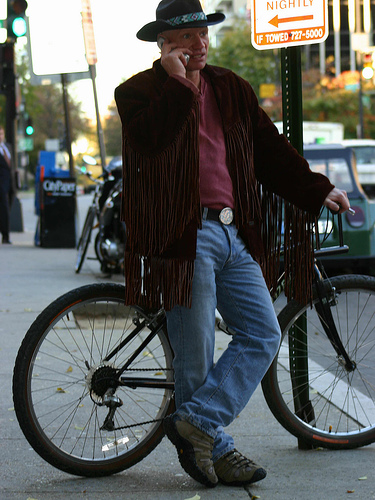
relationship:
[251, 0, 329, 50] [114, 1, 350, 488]
sign behind man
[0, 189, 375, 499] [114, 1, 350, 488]
sidewalk under man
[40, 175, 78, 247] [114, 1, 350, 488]
newspaper box behind man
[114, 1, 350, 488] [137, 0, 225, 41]
man wearing hat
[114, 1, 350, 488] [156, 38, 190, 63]
man talking on phone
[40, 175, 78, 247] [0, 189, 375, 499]
newspaper box on sidewalk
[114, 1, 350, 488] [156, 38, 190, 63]
man on phone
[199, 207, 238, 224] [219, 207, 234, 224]
belt and belt buckle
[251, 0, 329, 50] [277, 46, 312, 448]
sign on pole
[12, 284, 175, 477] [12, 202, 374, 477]
tire on bicycle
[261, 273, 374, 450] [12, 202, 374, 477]
front tire on bicycle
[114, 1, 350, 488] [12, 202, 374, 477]
man leaning against bicycle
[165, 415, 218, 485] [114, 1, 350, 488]
shoe of man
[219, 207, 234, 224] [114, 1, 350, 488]
belt buckle of man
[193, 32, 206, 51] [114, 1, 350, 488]
nose of man